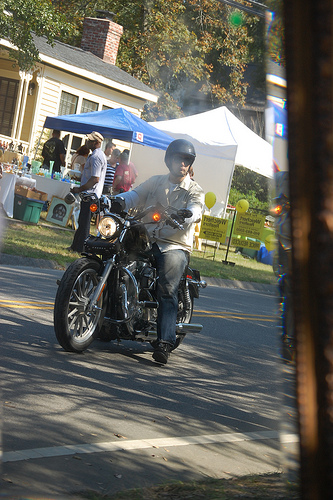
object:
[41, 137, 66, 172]
shirt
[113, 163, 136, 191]
shirt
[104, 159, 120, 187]
shirt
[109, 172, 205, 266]
shirt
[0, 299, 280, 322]
line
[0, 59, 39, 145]
porch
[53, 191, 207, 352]
motorcycle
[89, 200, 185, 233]
handlebars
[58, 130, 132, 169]
windows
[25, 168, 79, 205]
table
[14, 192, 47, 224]
bucket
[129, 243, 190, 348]
jeans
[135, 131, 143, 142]
sign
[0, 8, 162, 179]
home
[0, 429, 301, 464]
line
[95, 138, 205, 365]
man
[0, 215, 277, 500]
ground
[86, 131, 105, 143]
hat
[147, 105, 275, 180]
canopy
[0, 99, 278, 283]
yard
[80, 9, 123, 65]
chimney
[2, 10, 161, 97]
roof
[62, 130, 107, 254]
man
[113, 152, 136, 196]
man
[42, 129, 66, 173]
man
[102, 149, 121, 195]
man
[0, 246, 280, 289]
side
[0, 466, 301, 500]
side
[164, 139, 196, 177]
helmet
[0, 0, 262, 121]
tree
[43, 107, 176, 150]
blue canopy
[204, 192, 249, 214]
balloon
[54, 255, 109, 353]
tire